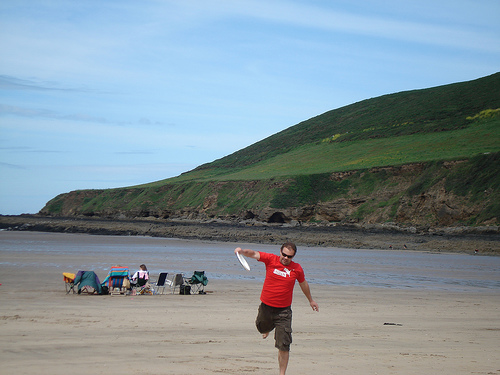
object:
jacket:
[76, 270, 104, 293]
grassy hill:
[35, 68, 499, 237]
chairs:
[181, 270, 206, 295]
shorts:
[256, 302, 292, 351]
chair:
[149, 270, 167, 296]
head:
[276, 242, 298, 267]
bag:
[179, 283, 192, 293]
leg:
[251, 303, 274, 336]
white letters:
[271, 269, 290, 279]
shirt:
[256, 251, 304, 308]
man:
[232, 242, 319, 375]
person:
[130, 262, 147, 279]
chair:
[129, 271, 148, 296]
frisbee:
[233, 251, 251, 272]